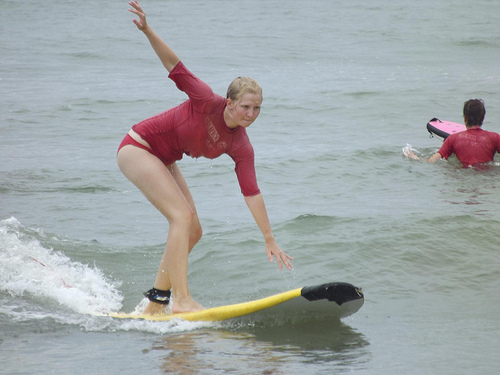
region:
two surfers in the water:
[3, 2, 498, 372]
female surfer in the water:
[96, 0, 374, 339]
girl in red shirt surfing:
[98, 0, 368, 333]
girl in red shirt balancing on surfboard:
[101, 3, 368, 337]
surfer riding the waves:
[105, 2, 370, 334]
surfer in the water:
[399, 90, 496, 178]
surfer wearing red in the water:
[399, 81, 498, 172]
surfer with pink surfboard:
[403, 90, 498, 165]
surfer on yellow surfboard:
[108, 2, 367, 341]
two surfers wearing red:
[94, 2, 496, 341]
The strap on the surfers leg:
[130, 279, 195, 327]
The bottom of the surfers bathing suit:
[121, 122, 155, 170]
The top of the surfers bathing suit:
[141, 56, 269, 216]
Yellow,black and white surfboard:
[78, 273, 372, 324]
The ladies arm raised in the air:
[121, 11, 218, 88]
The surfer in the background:
[415, 88, 495, 193]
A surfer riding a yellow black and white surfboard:
[112, 28, 374, 350]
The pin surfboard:
[432, 108, 466, 153]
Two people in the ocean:
[104, 28, 475, 373]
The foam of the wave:
[21, 236, 161, 347]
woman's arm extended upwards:
[124, 3, 209, 100]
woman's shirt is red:
[135, 27, 265, 198]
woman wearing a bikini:
[116, 129, 168, 165]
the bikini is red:
[113, 132, 160, 160]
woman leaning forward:
[67, 6, 310, 316]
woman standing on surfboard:
[69, 0, 373, 332]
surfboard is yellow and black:
[93, 263, 370, 340]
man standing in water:
[395, 96, 497, 171]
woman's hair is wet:
[221, 73, 270, 110]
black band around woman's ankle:
[136, 282, 176, 308]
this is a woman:
[89, 5, 311, 330]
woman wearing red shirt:
[119, 55, 283, 212]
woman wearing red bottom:
[94, 122, 187, 181]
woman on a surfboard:
[83, 10, 391, 355]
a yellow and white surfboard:
[83, 247, 370, 367]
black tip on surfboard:
[295, 258, 394, 339]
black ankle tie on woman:
[131, 271, 196, 356]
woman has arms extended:
[125, 2, 337, 264]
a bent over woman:
[83, 7, 325, 359]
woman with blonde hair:
[223, 64, 267, 121]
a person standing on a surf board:
[113, 1, 358, 322]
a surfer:
[123, 24, 382, 346]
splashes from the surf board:
[15, 245, 95, 310]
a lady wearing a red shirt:
[115, 40, 280, 286]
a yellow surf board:
[110, 265, 360, 316]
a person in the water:
[420, 106, 486, 156]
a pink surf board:
[420, 105, 451, 130]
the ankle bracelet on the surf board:
[145, 291, 170, 296]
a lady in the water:
[112, 26, 364, 341]